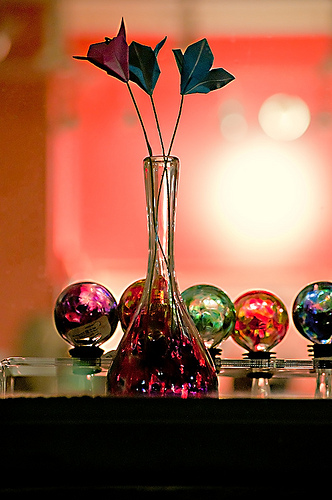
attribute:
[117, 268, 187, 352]
glass ball — orange, blown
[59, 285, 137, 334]
glass ball — colorful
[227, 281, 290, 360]
glass ball — colorful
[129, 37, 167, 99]
paper leafs — green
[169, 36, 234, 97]
paper leaves — green 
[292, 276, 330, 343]
sphere — blue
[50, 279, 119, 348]
ball — glass, colorful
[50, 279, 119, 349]
glass ball — colorful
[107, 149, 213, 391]
vase — glass 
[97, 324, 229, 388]
base — pink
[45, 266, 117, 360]
glass sphere — purple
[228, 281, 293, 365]
glass sphere — orange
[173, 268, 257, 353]
ball — green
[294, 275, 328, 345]
glass ball — colorful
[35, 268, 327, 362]
spheres — glass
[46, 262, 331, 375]
bulbs — colorful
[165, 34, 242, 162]
flower — blue , folded 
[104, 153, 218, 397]
vase — glass, flower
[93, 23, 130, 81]
flower — red, paper